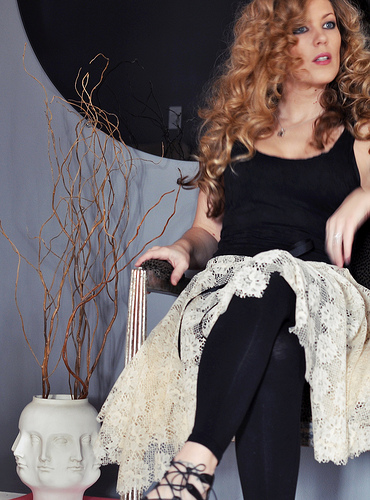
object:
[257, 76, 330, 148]
neck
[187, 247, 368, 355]
lap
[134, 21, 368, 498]
woman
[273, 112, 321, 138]
necklace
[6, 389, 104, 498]
white vase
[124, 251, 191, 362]
chair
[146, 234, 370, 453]
skirt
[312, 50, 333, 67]
pink lips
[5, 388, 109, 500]
container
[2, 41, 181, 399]
sticks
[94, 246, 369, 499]
shawl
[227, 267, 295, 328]
knee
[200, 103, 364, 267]
tank top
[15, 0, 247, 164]
mirror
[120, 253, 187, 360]
armrest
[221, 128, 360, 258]
woman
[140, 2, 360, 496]
top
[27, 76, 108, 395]
curely sticks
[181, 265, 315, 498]
tights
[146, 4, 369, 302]
woman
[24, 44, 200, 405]
branches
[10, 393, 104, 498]
planter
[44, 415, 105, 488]
face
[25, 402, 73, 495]
face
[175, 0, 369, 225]
curly hair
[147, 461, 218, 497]
shoes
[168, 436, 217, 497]
ankle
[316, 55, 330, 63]
teeth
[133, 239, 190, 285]
hand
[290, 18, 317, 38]
makeup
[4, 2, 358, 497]
wall